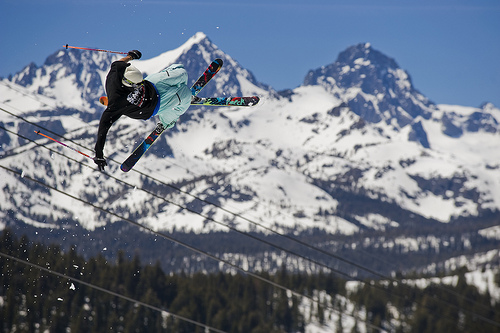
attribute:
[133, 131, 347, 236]
snow — white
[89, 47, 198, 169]
person — skiing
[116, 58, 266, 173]
skis — long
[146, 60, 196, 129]
pants — light blue, aqua, blue, skier's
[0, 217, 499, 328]
trees — pine trees, green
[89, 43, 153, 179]
arms — outstretched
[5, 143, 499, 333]
wires — black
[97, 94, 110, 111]
stick — orange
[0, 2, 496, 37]
sky — blue, clear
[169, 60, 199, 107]
knees — bent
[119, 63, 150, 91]
beanie — white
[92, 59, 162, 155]
sweatshirt — black